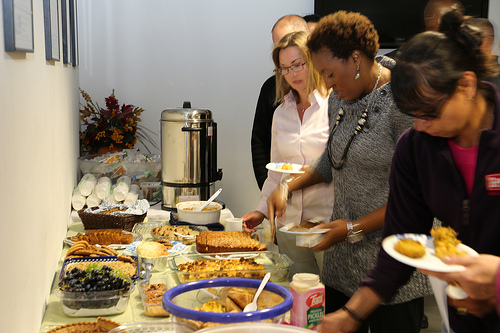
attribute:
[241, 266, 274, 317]
spoon — plastic, white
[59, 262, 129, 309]
grapes — purple, black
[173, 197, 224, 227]
dish — white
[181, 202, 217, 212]
food — yellow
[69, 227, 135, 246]
bread — plated, sliced, cut in slices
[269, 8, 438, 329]
woman — african, geting food, looking down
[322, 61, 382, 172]
necklace — silver, black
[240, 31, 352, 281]
woman — getting food, white, young, a blonde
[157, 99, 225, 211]
coffee dispenser — silver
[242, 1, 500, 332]
people — getting food, at a buffet table, in line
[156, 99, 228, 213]
urn — for coffee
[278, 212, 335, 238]
plate — paper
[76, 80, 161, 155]
flower arrangement — in corner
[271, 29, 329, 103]
hair — blonde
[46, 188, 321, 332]
food — a variety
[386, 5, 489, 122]
hair — pulled back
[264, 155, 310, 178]
plate — paper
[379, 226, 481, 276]
plate — being held, paper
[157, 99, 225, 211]
drink dispenser — silver, black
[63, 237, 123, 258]
cookies — stacked, baked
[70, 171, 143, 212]
cups — white, disposable, laying on sides, in packs, paper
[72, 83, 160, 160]
bouqet — flowers, autumn colored, in corner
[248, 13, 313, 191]
man — waiting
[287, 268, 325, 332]
container — pink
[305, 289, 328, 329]
label — colorful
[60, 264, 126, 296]
berries — dark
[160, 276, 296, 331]
container — plastic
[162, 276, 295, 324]
rim — purple